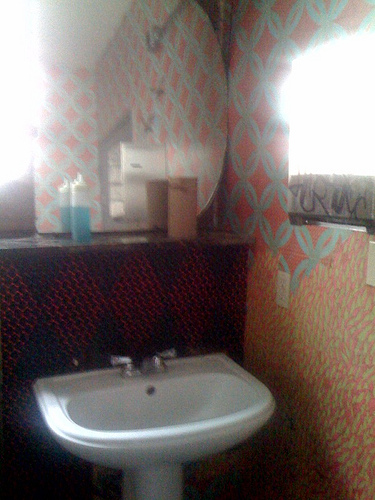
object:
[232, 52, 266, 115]
flowers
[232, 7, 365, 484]
paper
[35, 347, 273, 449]
sink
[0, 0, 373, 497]
bathroom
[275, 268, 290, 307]
outlet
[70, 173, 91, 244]
bottle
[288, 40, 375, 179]
mirror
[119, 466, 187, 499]
base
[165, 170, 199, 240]
paper roll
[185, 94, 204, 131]
diamonds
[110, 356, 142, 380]
faucets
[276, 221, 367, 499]
wall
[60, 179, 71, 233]
reflection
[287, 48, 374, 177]
light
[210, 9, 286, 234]
wall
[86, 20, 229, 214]
reflection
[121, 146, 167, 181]
cap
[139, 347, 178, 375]
faucet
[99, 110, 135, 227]
door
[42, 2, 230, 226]
mirror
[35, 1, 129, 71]
ceiling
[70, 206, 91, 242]
blue liquid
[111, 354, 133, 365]
handle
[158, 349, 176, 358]
handle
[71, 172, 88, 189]
cap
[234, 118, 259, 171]
diamond